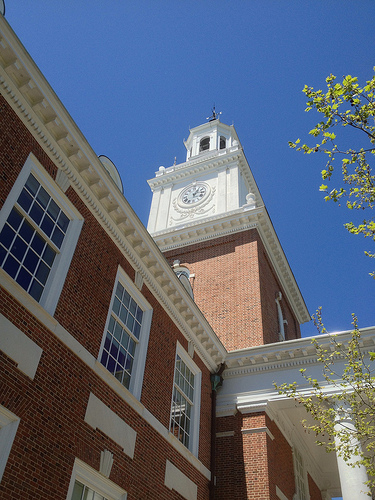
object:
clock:
[181, 185, 206, 205]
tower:
[145, 105, 314, 353]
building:
[1, 2, 373, 500]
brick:
[251, 449, 259, 451]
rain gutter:
[210, 363, 225, 500]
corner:
[208, 374, 221, 497]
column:
[331, 404, 375, 500]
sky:
[4, 2, 374, 340]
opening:
[199, 136, 210, 152]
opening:
[220, 136, 226, 151]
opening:
[190, 147, 193, 157]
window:
[1, 150, 87, 319]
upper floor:
[0, 92, 213, 481]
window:
[95, 263, 154, 404]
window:
[166, 337, 203, 461]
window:
[64, 455, 129, 499]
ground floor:
[1, 282, 216, 500]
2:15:
[190, 186, 206, 198]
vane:
[206, 101, 223, 122]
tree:
[272, 68, 374, 498]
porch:
[214, 324, 374, 500]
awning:
[212, 325, 374, 499]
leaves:
[333, 81, 345, 94]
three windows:
[1, 149, 203, 462]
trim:
[147, 204, 314, 328]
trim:
[1, 1, 374, 416]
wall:
[1, 92, 216, 498]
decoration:
[239, 425, 275, 443]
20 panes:
[1, 171, 74, 306]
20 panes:
[99, 279, 147, 397]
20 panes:
[167, 352, 197, 451]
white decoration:
[55, 168, 72, 194]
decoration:
[134, 270, 145, 292]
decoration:
[187, 341, 195, 358]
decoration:
[98, 449, 114, 479]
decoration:
[242, 188, 256, 211]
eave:
[148, 206, 313, 324]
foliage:
[271, 302, 374, 498]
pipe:
[210, 390, 217, 499]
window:
[273, 298, 287, 343]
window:
[96, 153, 125, 197]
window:
[175, 273, 195, 302]